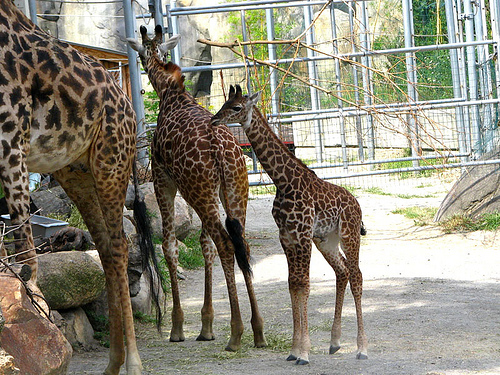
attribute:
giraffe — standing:
[210, 92, 375, 362]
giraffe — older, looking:
[136, 31, 259, 313]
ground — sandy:
[231, 221, 492, 367]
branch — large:
[198, 28, 449, 152]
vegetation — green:
[422, 19, 452, 93]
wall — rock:
[45, 8, 252, 110]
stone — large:
[20, 251, 106, 340]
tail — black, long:
[208, 136, 258, 279]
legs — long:
[152, 177, 270, 340]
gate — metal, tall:
[125, 2, 499, 179]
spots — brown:
[292, 179, 344, 223]